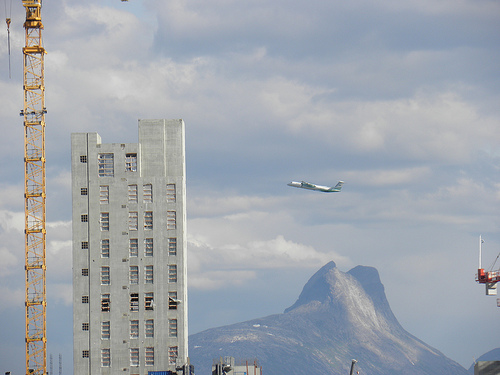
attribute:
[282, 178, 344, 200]
plane — flying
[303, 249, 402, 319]
mountain top — tall, peaked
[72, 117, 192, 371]
building — grey, under construction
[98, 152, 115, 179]
window — broken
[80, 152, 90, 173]
window — broken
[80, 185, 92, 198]
window — closed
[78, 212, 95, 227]
window — broken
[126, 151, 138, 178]
window — closed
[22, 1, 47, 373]
yellow crane — tall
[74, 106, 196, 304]
tower — big, gray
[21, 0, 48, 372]
construction equipment — tall, yellow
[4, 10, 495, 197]
cloud — white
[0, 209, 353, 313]
cloud — white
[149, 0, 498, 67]
cloud — white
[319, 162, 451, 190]
cloud — white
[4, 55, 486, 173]
cloud — white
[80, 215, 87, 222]
window — closed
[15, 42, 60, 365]
ladder — yellow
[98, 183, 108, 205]
window — broken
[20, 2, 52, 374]
equipment — yellow, construction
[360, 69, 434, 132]
clouds — white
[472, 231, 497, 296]
equipment — red, white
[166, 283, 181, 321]
window — broken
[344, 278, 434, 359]
slope — steep